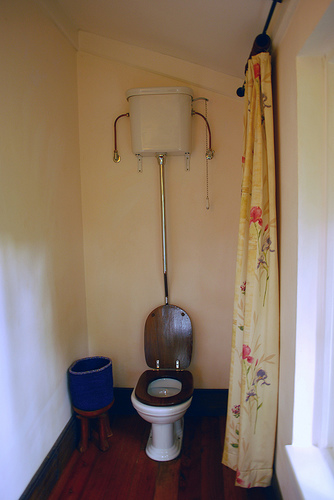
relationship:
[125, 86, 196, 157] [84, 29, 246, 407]
tank mounted high on wall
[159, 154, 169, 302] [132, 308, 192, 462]
pipe connects tank to toilet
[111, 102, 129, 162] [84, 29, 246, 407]
pipe connected to wall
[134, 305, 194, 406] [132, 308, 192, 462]
seat of toilet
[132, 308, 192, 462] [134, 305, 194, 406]
toilet has a seat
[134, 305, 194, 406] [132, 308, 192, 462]
seat on toilet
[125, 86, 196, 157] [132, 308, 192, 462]
tank for toilet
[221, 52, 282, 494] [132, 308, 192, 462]
curtain next to toilet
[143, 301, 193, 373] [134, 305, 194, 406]
lid to seat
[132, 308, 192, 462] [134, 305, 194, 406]
toilet has a wood seat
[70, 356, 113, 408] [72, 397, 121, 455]
basket on a stool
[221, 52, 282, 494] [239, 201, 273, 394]
curtain has flowers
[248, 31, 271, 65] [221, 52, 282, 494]
rings on curtain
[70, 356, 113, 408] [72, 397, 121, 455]
basket on stool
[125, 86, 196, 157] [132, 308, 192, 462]
tank above toilet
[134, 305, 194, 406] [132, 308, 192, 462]
seat for toilet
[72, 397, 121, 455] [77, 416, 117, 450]
stool has legs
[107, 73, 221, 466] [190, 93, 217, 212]
toilet has chain